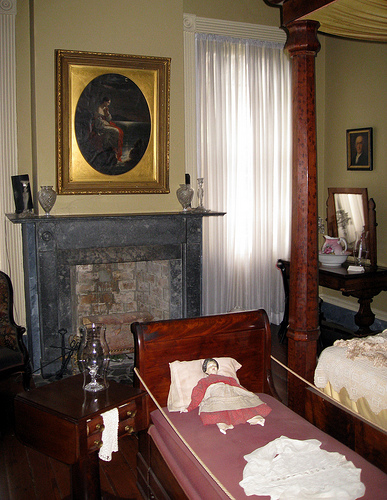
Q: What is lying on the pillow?
A: Doll.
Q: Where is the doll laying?
A: Pillow.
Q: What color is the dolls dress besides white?
A: Red.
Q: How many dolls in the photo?
A: One.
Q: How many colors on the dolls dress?
A: Two.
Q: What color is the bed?
A: Brown.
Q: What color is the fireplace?
A: Gray.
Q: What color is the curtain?
A: White.